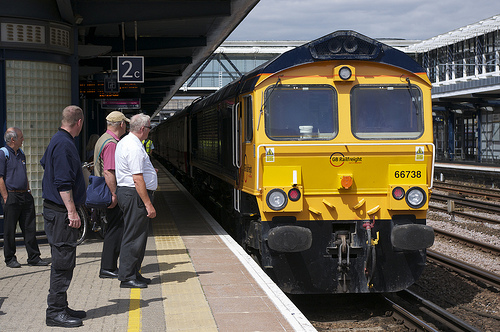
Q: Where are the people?
A: At a train station.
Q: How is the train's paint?
A: Yellow.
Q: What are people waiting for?
A: The train.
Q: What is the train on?
A: Tracks.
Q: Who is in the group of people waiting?
A: A group of men.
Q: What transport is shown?
A: A train.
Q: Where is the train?
A: On the tracks.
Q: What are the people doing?
A: Waiting.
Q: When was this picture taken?
A: Afternoon.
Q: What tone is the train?
A: Yellow.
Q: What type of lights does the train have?
A: Headlights.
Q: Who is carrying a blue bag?
A: A man in a cap.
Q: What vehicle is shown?
A: Train.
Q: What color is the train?
A: Yellow.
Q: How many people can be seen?
A: 4.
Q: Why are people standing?
A: Waiting to board the train.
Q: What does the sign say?
A: 2c.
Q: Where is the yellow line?
A: On the platform.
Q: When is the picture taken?
A: Daytime.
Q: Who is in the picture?
A: Men.